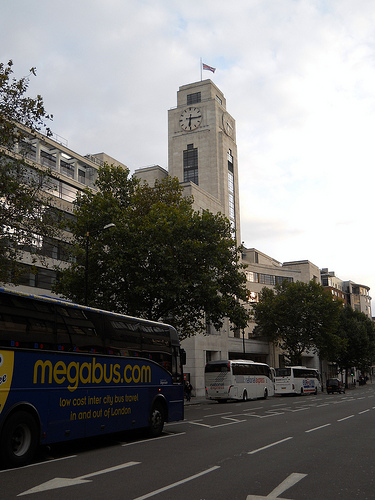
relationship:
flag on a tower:
[204, 63, 216, 74] [168, 78, 240, 241]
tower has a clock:
[168, 78, 240, 241] [179, 105, 202, 130]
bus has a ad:
[1, 286, 186, 462] [32, 358, 152, 394]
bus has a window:
[1, 286, 186, 462] [68, 311, 98, 351]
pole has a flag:
[200, 65, 206, 83] [204, 63, 216, 74]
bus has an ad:
[1, 286, 186, 462] [34, 358, 151, 384]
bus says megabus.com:
[1, 286, 186, 462] [32, 358, 154, 386]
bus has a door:
[1, 286, 186, 462] [165, 350, 183, 412]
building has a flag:
[168, 82, 238, 237] [204, 63, 216, 74]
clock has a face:
[179, 105, 202, 130] [184, 114, 201, 128]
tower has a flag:
[168, 78, 240, 241] [204, 63, 216, 74]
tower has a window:
[168, 78, 240, 241] [182, 143, 200, 186]